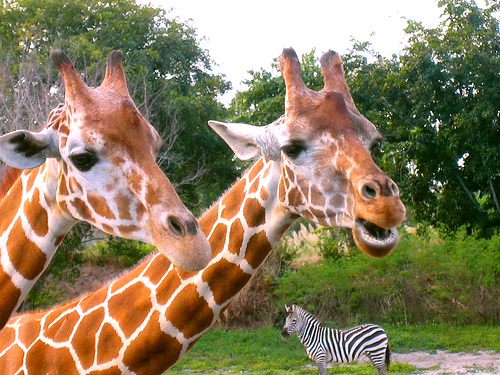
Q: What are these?
A: Giraffes.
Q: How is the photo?
A: Clear.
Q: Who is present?
A: No one.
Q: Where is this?
A: Outdoors.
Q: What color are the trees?
A: Green.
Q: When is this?
A: Daytime.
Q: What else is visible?
A: Zebra.